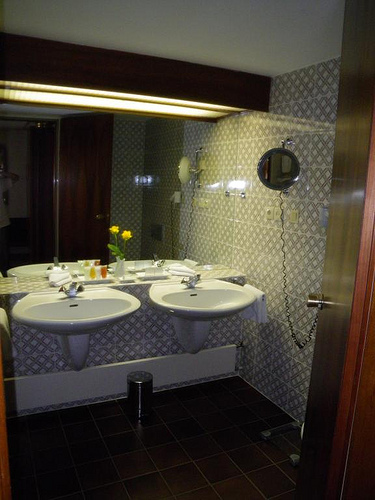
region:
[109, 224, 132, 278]
the two yellow flowers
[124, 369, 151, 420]
the silver trash can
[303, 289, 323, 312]
the knob on the door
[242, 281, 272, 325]
the towel beside the sink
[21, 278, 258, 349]
the double sinks side by side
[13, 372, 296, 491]
tile on the floor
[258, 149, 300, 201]
round mirror on the wall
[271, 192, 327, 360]
cord hanging from the round mirror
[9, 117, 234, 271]
the large bathroom mirror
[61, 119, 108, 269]
the image of the door in the mirror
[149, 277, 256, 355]
right pedestal sink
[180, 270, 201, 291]
right pedestals sink faucets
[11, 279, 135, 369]
left pedestal sink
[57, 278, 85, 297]
left pedestal sink faucets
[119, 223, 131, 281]
yellow flower in a vase on wall against mirror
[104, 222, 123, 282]
reflection of yellow flower in vase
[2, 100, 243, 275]
large wall mirror in front of double sinks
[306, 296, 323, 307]
door knob on wooden door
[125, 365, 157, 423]
trash can under the double sink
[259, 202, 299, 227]
electrical switches on wall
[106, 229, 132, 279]
Yellow flower in a white vase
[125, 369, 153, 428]
Small silver trash can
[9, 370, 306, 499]
Dark tiled bathroom floor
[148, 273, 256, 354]
White sink mounted to the wall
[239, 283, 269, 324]
Small white towel on rack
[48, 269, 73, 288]
Folded washrags on ledge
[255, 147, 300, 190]
Circular mirror hangs on wall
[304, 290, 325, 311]
Silver door handle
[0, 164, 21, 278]
Reflection of person in white shirt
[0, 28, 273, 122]
Large overhead light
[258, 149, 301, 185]
a swivel mirror mounted on a wall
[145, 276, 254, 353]
a white porcelain sink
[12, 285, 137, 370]
a white porcelain sink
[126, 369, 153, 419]
a small silver waste basket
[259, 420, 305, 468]
a glass scale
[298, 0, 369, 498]
a tall wooden door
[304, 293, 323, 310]
a shiny silver door knob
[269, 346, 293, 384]
a gray and white tile on a wall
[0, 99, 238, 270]
a large mirror on a wall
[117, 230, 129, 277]
a vase with a yellow flower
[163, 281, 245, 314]
a sink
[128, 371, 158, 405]
a trash can on the floor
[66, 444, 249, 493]
tile on the floor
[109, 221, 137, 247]
the flowers are yellow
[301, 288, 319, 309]
a door handle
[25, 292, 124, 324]
the left sink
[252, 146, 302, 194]
a mirror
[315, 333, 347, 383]
the door is brown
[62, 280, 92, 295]
a faucet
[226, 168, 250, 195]
a reflection of light on the mirror